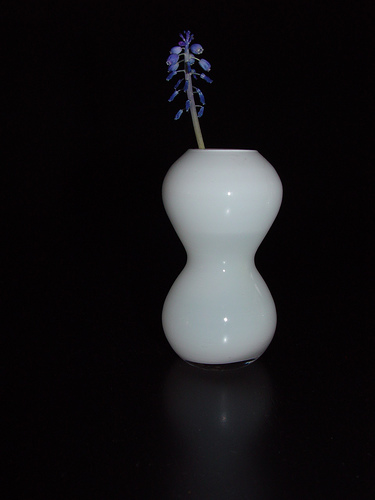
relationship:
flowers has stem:
[163, 22, 212, 126] [182, 68, 211, 151]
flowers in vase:
[163, 22, 212, 126] [163, 135, 287, 368]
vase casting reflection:
[159, 148, 285, 372] [173, 364, 275, 490]